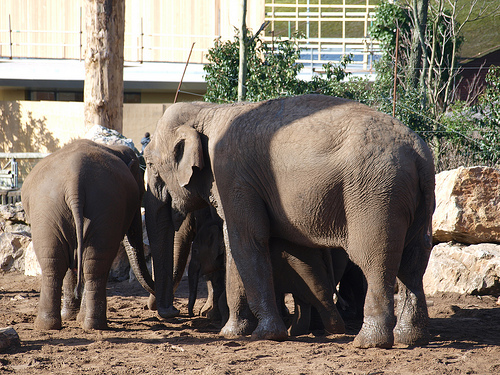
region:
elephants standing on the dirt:
[11, 99, 447, 362]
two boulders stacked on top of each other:
[423, 164, 499, 296]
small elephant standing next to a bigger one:
[8, 96, 455, 353]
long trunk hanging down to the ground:
[135, 182, 189, 328]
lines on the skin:
[352, 153, 405, 210]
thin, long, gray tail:
[55, 196, 97, 311]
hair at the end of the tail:
[69, 282, 86, 304]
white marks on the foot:
[357, 309, 389, 343]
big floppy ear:
[164, 126, 206, 191]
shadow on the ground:
[426, 307, 499, 346]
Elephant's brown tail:
[54, 179, 92, 301]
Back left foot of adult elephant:
[344, 307, 399, 354]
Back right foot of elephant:
[382, 316, 441, 352]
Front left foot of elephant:
[245, 313, 293, 343]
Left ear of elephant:
[166, 127, 208, 209]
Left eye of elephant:
[142, 155, 157, 172]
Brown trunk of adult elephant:
[141, 184, 190, 323]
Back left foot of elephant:
[29, 306, 64, 340]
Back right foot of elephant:
[78, 312, 117, 334]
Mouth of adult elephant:
[152, 186, 191, 237]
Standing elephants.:
[18, 85, 443, 351]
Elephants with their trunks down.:
[105, 105, 212, 325]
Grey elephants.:
[20, 90, 441, 350]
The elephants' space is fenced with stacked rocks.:
[1, 170, 496, 290]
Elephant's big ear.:
[167, 120, 202, 185]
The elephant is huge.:
[140, 91, 436, 346]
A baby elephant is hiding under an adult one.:
[185, 215, 345, 335]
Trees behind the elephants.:
[210, 2, 450, 92]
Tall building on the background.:
[256, 0, 402, 85]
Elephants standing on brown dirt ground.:
[18, 88, 439, 349]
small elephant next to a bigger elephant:
[15, 88, 440, 357]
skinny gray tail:
[61, 191, 94, 299]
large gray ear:
[159, 126, 206, 187]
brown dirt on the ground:
[0, 290, 495, 373]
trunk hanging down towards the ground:
[140, 180, 186, 323]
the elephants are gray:
[47, 72, 480, 369]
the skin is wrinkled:
[162, 86, 405, 368]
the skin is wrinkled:
[285, 124, 420, 286]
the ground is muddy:
[56, 304, 208, 366]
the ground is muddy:
[104, 302, 252, 372]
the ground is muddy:
[376, 332, 438, 371]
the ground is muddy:
[245, 344, 325, 372]